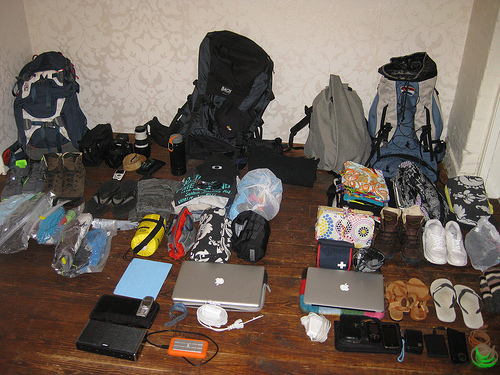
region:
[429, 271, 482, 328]
white sandals with black straps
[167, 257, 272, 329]
grey Apple branded personal computer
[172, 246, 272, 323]
Apple branded laptop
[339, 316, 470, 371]
group of black electronic devices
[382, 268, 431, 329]
tan sandals with brown straps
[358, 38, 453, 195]
light blue and grey backpack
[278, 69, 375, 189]
grey backpack with black straps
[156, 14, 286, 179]
black and grey backpack with pockets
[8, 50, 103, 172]
dark blue and white backpack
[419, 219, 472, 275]
white tennis shoes with white shoelaces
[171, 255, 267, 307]
Laptop computer sitting on a floor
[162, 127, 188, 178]
Drink bottle sitting on the floor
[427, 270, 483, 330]
Someone's thongs ready to be packed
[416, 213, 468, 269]
White tennis shoes ready to be packed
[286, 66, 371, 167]
Backpack ready for a hiking trip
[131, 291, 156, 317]
Cell phone charged and ready for use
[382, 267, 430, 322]
Sandals for use at the beach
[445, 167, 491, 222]
Towels for use after going swimming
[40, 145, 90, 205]
Boots used for trail hiking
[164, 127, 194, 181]
Drinking bottle ice cold water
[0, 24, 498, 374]
a bunch of hostel-visitor type property stacked on a table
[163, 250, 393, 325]
two apple laptops @ center, one has curious striped knit thing beneath it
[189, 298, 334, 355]
two white ac adaptors, wound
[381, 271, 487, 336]
zoris [flipflops] beside sandals, lower right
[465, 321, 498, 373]
something fluoro green, twisty+ wound beside something smaller w/ a red pattern, twisty+wound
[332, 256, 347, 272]
cross sign on navy neoprene case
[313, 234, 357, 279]
case with cross on it also has red trim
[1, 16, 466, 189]
four backpacks in four different shades of black - white - grey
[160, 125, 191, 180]
a bottle, probably a thermos, w/ some sort of orange strap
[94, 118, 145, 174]
a black camera barely perceptible near back wall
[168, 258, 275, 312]
a laptop on the floor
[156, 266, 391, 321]
two laptops on the floor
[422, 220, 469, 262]
a pair of white tennis shoes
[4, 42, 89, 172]
a back pack against the wall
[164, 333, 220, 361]
a cell phone with a orange cover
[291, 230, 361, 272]
a blue and red first aid kit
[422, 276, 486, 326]
a pair of flip flops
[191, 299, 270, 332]
a computer cable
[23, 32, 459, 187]
four back packs leaning against a wall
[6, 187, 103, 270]
several items of clothing in plastic bags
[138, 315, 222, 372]
small orange electrical device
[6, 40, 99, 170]
blue and white bag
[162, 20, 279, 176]
blue and silver bag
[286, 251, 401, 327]
small silver laptop computer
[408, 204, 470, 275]
plain white tennis shoes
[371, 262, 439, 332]
pair of brown sandals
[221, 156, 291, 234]
plastic bag of clothes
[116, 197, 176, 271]
small yellow travel pack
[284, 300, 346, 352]
small white wall charger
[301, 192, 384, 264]
colorful bag with design